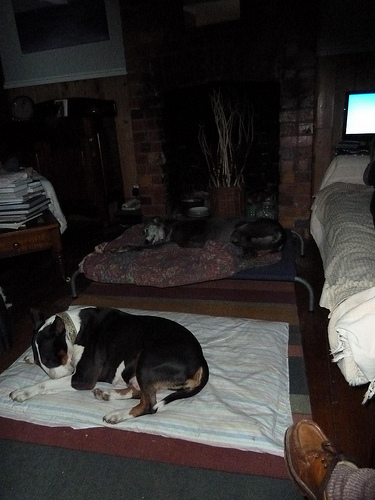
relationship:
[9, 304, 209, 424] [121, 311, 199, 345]
dog has back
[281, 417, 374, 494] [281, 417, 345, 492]
person wearing shoe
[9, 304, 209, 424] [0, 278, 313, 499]
dog on bed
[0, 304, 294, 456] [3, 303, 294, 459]
bed has stripes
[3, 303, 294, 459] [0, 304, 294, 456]
stripes on bed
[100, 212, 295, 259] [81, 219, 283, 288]
dog sleeping on dog bed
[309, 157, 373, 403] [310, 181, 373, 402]
bed has bedding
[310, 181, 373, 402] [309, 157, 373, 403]
bedding on bed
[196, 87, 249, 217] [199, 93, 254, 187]
decoration has tree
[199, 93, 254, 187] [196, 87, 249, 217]
tree on decoration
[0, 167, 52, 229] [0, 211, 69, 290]
books laying on table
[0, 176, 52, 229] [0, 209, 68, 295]
books laying on table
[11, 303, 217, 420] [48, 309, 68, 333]
dog has an ear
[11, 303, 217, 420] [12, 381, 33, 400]
dog has paw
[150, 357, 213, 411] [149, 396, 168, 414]
dog's tail has tip